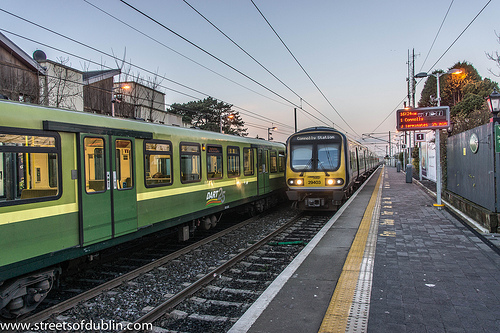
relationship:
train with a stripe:
[8, 95, 282, 314] [7, 164, 277, 229]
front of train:
[283, 125, 348, 209] [283, 120, 379, 199]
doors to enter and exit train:
[72, 126, 146, 251] [8, 95, 282, 314]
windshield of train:
[290, 136, 340, 171] [280, 123, 380, 214]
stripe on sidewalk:
[315, 170, 385, 331] [258, 153, 463, 323]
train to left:
[8, 95, 282, 314] [7, 8, 280, 318]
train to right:
[280, 123, 380, 214] [280, 120, 381, 205]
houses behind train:
[0, 48, 209, 124] [8, 95, 282, 314]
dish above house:
[33, 44, 47, 62] [35, 49, 92, 112]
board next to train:
[395, 104, 452, 131] [283, 120, 379, 199]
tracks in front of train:
[141, 215, 319, 323] [280, 126, 353, 205]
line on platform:
[314, 161, 390, 329] [217, 159, 496, 329]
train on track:
[280, 123, 380, 214] [127, 158, 379, 321]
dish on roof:
[33, 48, 47, 62] [34, 54, 85, 79]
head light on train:
[323, 173, 341, 188] [280, 123, 380, 214]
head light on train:
[287, 177, 303, 187] [280, 123, 380, 214]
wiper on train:
[317, 160, 329, 179] [280, 123, 380, 214]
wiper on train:
[295, 157, 312, 177] [280, 123, 380, 214]